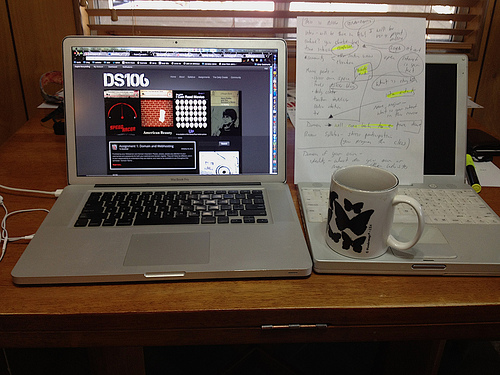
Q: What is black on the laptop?
A: The keys.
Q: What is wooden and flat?
A: The surface.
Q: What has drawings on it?
A: The paper.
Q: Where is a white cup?
A: On a desk.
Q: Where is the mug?
A: On the computer.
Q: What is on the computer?
A: A mug.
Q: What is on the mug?
A: A handle.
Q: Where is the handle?
A: On the mug.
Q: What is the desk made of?
A: Wood.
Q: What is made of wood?
A: The desk.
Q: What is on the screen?
A: An image.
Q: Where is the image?
A: On the screen.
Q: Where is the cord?
A: Plugged into the computer.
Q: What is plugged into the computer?
A: A cord.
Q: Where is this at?
A: A work office.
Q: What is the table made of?
A: Wood.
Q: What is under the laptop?
A: Desk.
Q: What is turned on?
A: Laptop.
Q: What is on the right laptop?
A: Paper with notes.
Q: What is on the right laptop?
A: A coffee cup.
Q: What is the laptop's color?
A: Gray.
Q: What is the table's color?
A: Brown.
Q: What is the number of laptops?
A: 2.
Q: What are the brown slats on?
A: Blinds.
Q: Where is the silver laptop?
A: On a desk.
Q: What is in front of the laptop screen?
A: A piece of paper.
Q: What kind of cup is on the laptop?
A: A black and white coffee cup.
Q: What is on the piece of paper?
A: Writing.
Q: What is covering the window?
A: A mini blind.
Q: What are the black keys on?
A: A laptop.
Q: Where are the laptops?
A: On a desk.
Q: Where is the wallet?
A: By the highlighter.